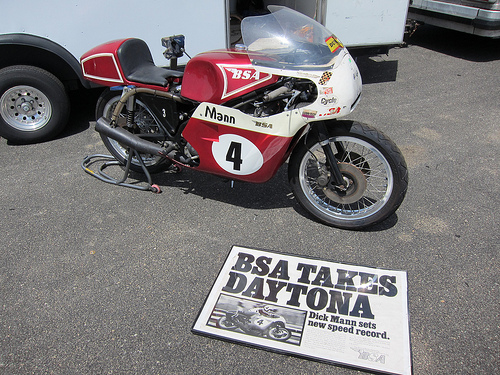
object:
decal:
[190, 104, 241, 130]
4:
[225, 141, 242, 170]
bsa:
[232, 70, 260, 80]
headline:
[221, 252, 397, 320]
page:
[193, 246, 412, 374]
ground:
[0, 45, 498, 371]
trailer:
[0, 0, 410, 144]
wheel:
[287, 120, 408, 230]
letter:
[230, 252, 254, 273]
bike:
[82, 3, 407, 230]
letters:
[205, 106, 217, 120]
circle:
[212, 134, 264, 176]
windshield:
[232, 38, 335, 102]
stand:
[81, 147, 184, 193]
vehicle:
[404, 0, 500, 39]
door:
[229, 2, 323, 49]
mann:
[205, 105, 236, 124]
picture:
[206, 293, 307, 344]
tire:
[287, 120, 409, 230]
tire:
[94, 86, 185, 174]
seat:
[118, 37, 184, 86]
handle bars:
[261, 86, 290, 104]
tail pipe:
[94, 116, 190, 164]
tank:
[180, 47, 280, 104]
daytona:
[221, 271, 375, 319]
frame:
[190, 243, 412, 374]